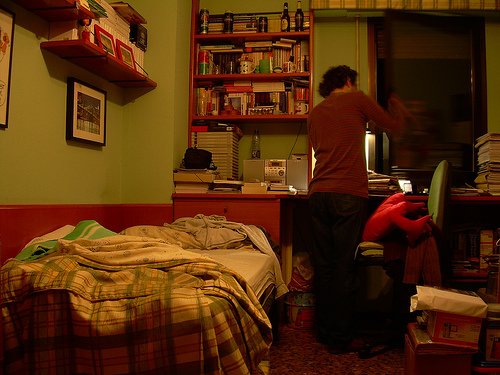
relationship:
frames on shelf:
[93, 25, 136, 70] [40, 41, 156, 88]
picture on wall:
[59, 77, 114, 153] [7, 5, 173, 234]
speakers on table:
[243, 159, 309, 191] [180, 187, 295, 251]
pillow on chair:
[372, 176, 430, 266] [353, 164, 454, 313]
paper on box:
[409, 285, 489, 318] [395, 321, 472, 373]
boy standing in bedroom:
[306, 65, 406, 356] [4, 2, 498, 365]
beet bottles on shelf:
[193, 2, 310, 34] [191, 30, 313, 37]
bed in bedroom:
[0, 215, 282, 373] [4, 2, 498, 365]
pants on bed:
[150, 196, 264, 295] [0, 215, 282, 373]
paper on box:
[412, 283, 486, 318] [428, 316, 488, 346]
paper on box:
[412, 283, 486, 318] [403, 325, 438, 362]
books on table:
[472, 132, 496, 199] [454, 183, 498, 286]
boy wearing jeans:
[306, 65, 406, 356] [299, 177, 373, 357]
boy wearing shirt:
[306, 65, 406, 356] [300, 93, 412, 203]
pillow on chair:
[364, 193, 432, 244] [351, 148, 465, 340]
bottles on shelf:
[278, 2, 308, 32] [165, 0, 332, 178]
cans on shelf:
[276, 54, 316, 79] [165, 0, 332, 178]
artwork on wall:
[52, 73, 114, 150] [7, 5, 173, 234]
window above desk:
[366, 11, 488, 184] [174, 186, 499, 321]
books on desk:
[473, 130, 499, 194] [171, 190, 498, 288]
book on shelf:
[241, 40, 275, 48] [184, 1, 315, 140]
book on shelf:
[242, 46, 273, 55] [184, 1, 315, 140]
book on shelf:
[197, 43, 232, 53] [184, 1, 315, 140]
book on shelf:
[293, 43, 300, 72] [184, 1, 315, 140]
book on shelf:
[282, 47, 287, 74] [184, 1, 315, 140]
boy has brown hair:
[301, 57, 406, 350] [319, 66, 358, 96]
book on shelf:
[241, 40, 275, 46] [192, 72, 311, 77]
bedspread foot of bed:
[0, 238, 280, 373] [0, 215, 282, 373]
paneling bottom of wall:
[0, 201, 173, 266] [2, 179, 294, 349]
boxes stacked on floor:
[412, 283, 486, 357] [248, 319, 474, 373]